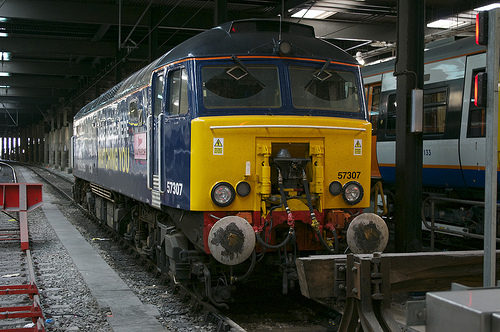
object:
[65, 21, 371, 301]
train engine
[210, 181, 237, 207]
headlight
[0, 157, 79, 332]
track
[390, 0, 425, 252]
post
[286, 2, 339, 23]
light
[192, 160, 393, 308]
bumper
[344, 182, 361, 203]
headlight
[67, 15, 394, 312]
train's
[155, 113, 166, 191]
metal handle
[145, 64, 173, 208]
door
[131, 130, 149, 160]
sign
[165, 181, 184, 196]
numbers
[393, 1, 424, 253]
beam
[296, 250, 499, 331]
barrier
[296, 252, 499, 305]
wood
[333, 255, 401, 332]
metal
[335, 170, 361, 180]
number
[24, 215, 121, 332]
rocks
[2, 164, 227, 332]
ground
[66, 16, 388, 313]
blue train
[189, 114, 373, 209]
yellow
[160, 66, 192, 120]
window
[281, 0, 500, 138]
area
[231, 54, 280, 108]
wiper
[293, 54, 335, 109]
wiper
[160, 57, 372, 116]
windshield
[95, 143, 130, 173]
writing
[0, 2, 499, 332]
lot